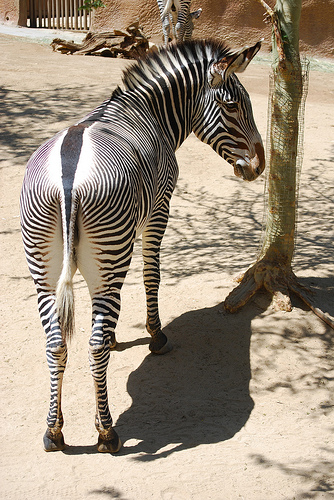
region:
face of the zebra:
[182, 54, 259, 179]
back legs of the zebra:
[36, 396, 180, 478]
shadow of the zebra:
[135, 334, 291, 466]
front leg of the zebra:
[137, 298, 181, 350]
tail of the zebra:
[51, 184, 89, 361]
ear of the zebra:
[227, 44, 261, 82]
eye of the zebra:
[218, 83, 240, 130]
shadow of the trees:
[252, 442, 322, 498]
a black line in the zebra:
[51, 129, 93, 192]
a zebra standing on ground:
[23, 27, 307, 487]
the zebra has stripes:
[114, 40, 305, 334]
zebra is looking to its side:
[103, 52, 299, 257]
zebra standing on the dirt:
[14, 32, 268, 461]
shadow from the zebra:
[50, 282, 273, 470]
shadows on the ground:
[247, 446, 331, 498]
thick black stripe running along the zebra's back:
[52, 101, 114, 220]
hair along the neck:
[103, 32, 229, 94]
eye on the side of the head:
[225, 101, 236, 112]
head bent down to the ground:
[180, 5, 206, 43]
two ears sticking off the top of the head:
[202, 33, 266, 88]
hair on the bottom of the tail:
[52, 282, 82, 339]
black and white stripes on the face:
[193, 52, 280, 187]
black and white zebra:
[15, 24, 265, 452]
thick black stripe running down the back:
[55, 104, 105, 220]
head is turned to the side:
[185, 32, 276, 184]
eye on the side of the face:
[224, 101, 240, 114]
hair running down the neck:
[103, 24, 232, 98]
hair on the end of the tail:
[55, 287, 77, 340]